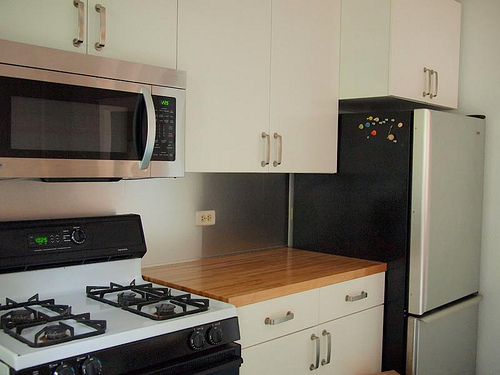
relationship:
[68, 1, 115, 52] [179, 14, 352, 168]
handles attached to cabinet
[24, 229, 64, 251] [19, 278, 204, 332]
clock attached to stove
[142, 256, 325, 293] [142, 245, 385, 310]
butcher block on top of butcher block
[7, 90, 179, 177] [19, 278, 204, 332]
microwave above stove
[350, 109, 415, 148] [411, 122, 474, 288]
magnets on side of refrigerator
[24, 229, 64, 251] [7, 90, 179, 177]
clock attached to microwave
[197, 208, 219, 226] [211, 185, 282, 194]
outlet attached to wall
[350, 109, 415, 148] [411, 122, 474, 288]
magnets attached to refrigerator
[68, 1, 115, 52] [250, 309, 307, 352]
handles attached to drawer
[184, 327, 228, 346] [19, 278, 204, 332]
knobs attached to stove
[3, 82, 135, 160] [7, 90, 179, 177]
door attached to microwave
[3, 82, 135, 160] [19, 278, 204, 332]
door attached to stove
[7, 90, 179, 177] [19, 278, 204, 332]
microwave over stove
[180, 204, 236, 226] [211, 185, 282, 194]
outlet attached to wall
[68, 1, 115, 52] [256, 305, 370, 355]
handles attached to cabinets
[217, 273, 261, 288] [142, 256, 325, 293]
lines on cupboard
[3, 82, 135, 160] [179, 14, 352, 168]
door attached to cabinet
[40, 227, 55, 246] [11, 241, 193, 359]
light attached to stove top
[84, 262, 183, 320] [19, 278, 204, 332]
burners on top of stove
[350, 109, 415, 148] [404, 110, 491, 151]
magnets attached to fridge